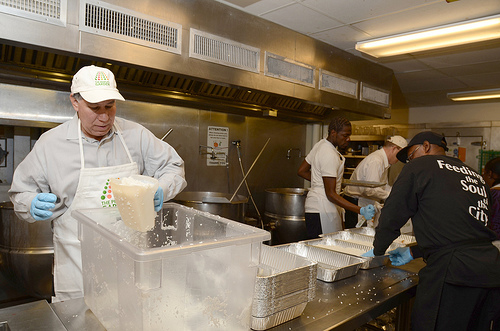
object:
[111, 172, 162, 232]
pitcher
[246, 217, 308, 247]
stove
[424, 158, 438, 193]
ground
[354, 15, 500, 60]
ceiling light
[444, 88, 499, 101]
ceiling light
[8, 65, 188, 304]
chef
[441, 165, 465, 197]
ground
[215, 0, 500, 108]
ceiling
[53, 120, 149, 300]
apron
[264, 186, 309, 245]
containers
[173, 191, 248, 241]
containers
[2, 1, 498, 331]
food bank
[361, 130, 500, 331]
man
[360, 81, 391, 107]
vent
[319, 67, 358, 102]
vent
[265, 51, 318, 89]
vent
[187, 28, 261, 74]
vent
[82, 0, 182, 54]
vent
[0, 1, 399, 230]
wall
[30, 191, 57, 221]
gloves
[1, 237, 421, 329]
counter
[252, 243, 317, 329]
pans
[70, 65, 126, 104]
baseball cap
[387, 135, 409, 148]
baseball cap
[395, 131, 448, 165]
baseball cap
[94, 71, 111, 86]
logo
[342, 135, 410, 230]
people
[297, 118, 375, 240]
people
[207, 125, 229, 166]
paper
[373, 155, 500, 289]
shirt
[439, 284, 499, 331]
pants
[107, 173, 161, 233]
batter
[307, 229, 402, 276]
batter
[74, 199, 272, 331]
container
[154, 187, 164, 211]
gloves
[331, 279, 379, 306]
crumbs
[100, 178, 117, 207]
logo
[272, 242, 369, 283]
aluminum pan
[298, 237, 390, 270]
aluminum pan